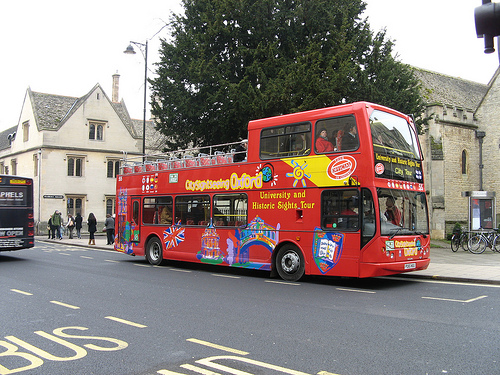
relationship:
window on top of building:
[67, 156, 83, 175] [19, 91, 128, 246]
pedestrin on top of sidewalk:
[85, 214, 96, 245] [71, 237, 111, 248]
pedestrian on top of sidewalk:
[85, 214, 96, 245] [71, 237, 111, 248]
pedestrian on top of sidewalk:
[105, 215, 114, 243] [71, 237, 111, 248]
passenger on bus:
[237, 136, 250, 160] [114, 101, 433, 284]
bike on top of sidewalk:
[469, 231, 499, 252] [445, 255, 498, 278]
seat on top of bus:
[195, 151, 213, 169] [114, 101, 433, 284]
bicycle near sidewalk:
[469, 231, 499, 252] [71, 237, 111, 248]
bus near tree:
[114, 101, 433, 284] [151, 4, 433, 113]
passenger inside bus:
[315, 131, 335, 156] [114, 101, 433, 284]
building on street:
[19, 91, 128, 246] [33, 246, 112, 272]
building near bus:
[432, 64, 500, 237] [114, 101, 433, 284]